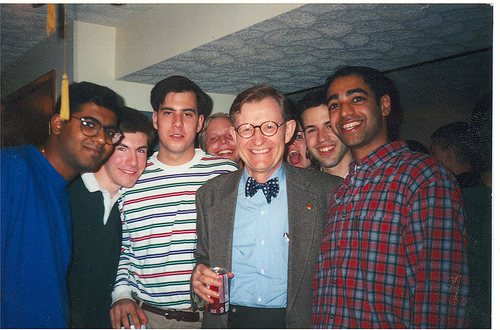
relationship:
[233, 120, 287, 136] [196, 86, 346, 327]
glasses on old man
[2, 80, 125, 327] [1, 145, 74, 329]
man wearing blue shirt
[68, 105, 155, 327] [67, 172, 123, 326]
man wearing black shirt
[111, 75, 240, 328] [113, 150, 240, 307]
man wearing striped shirt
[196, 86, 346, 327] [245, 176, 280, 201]
old man wearing bow tie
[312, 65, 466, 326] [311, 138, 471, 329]
man wearing plaid shirt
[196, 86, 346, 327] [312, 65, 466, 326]
old man next to man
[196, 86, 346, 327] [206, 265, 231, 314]
old man holding soda can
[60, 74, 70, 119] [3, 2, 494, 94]
tassel handing from ceiling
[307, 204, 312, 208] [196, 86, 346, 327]
red pin on old man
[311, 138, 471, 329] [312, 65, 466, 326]
plaid shirt on man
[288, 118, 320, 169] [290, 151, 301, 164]
person has open mouth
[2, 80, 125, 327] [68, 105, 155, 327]
man posing next to man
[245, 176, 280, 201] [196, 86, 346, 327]
bow tie on old man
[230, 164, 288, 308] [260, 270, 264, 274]
light blue shirt has button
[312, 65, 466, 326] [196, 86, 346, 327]
man posing with old man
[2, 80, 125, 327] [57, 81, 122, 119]
man has black hair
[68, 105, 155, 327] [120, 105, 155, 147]
man has brown hair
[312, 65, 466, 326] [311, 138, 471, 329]
man in plaid shirt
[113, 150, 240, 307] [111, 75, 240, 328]
striped shirt on man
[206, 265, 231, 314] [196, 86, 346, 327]
soda can held by old man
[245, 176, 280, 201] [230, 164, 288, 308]
bow tie over light blue shirt